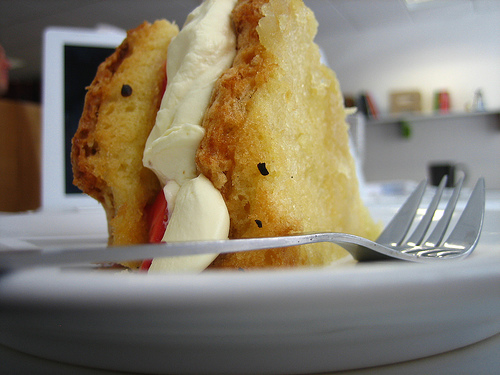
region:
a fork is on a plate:
[15, 170, 487, 270]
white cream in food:
[140, 1, 249, 271]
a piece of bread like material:
[75, 21, 174, 272]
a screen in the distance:
[38, 26, 150, 213]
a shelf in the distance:
[367, 108, 499, 132]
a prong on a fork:
[442, 176, 487, 253]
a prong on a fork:
[377, 174, 425, 260]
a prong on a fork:
[408, 176, 447, 248]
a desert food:
[89, 9, 377, 271]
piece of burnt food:
[255, 163, 267, 175]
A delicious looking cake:
[93, 18, 355, 239]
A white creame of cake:
[175, 191, 232, 256]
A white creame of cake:
[152, 58, 198, 139]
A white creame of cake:
[175, 9, 239, 89]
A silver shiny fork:
[185, 157, 483, 291]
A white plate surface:
[319, 268, 470, 349]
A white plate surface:
[76, 288, 265, 354]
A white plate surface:
[2, 204, 57, 255]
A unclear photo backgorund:
[356, 21, 484, 142]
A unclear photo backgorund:
[10, 14, 132, 82]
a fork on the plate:
[0, 168, 494, 280]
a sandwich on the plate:
[71, 10, 374, 277]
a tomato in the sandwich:
[145, 185, 167, 265]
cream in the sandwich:
[142, 0, 236, 279]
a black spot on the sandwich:
[253, 154, 274, 176]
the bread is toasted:
[208, 2, 376, 266]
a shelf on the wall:
[350, 80, 497, 140]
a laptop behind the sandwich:
[32, 22, 128, 241]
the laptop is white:
[21, 20, 113, 253]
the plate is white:
[2, 228, 497, 370]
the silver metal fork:
[2, 178, 494, 274]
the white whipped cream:
[137, 0, 243, 272]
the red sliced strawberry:
[140, 181, 175, 278]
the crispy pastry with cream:
[54, 2, 384, 269]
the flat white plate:
[3, 204, 498, 370]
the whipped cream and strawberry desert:
[146, 0, 239, 273]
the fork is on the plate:
[0, 175, 496, 310]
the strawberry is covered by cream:
[145, 190, 180, 271]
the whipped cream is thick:
[142, 0, 237, 276]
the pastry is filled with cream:
[70, 0, 380, 266]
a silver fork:
[11, 172, 488, 269]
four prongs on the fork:
[368, 172, 490, 258]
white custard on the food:
[151, 0, 233, 269]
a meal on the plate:
[78, 0, 380, 264]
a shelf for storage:
[361, 90, 498, 120]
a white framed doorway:
[41, 27, 120, 198]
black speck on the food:
[255, 159, 270, 179]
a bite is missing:
[72, 170, 124, 257]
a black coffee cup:
[427, 160, 465, 186]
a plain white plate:
[0, 241, 495, 371]